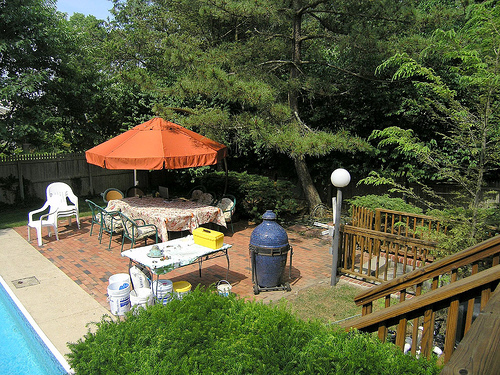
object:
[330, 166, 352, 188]
yard light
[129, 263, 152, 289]
bucket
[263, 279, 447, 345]
grass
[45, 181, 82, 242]
stack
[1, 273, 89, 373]
pool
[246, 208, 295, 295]
cleaning equipment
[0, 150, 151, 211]
privacy fence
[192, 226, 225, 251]
box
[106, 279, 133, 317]
bucket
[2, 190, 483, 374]
ground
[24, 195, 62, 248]
chair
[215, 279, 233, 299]
bucket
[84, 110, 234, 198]
umbrella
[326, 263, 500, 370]
railing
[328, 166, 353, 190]
ball light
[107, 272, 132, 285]
bucket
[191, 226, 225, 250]
toolbox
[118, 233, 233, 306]
table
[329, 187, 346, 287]
post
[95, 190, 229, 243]
dining table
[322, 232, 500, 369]
stairs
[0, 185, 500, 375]
backyard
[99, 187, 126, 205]
chairs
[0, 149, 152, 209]
fence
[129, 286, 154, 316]
bucket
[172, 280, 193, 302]
bucket